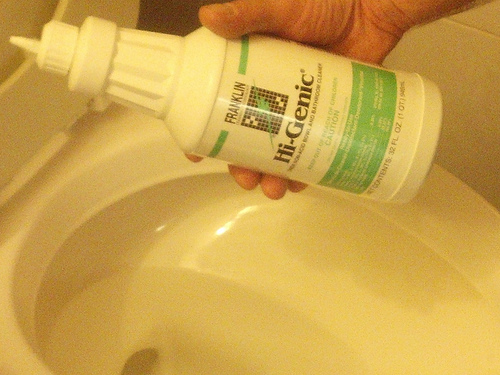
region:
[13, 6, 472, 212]
white green and black bottle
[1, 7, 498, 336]
toilet in background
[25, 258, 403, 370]
water in toilet bowl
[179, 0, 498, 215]
hand holding white bottle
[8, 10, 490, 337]
yellowish tint in background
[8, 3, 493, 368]
white toilet in background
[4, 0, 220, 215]
toilet seat put up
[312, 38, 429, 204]
green label on white bottle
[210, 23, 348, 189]
logo on white bottle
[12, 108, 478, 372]
clear water in toilet bowl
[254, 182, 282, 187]
section of two fingers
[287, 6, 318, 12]
section of a thumb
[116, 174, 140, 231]
inside of a sink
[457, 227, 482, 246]
edge of a sink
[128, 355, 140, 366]
hole on a sink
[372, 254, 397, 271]
a white sink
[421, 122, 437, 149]
bottom of a bottle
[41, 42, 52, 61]
tip of a bottle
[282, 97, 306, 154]
name of a white bottle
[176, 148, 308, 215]
four fingers holding bottle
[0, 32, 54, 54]
pointy tip of bottle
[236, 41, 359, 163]
writing on bottle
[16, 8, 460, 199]
white and green bottle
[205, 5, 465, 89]
hand holding bottle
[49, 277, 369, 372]
water in clean toilet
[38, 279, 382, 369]
clean water in toilet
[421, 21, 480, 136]
white wall by hand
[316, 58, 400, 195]
green block area on bottle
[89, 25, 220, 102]
neck of white bottle by toilet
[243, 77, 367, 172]
this is a bottle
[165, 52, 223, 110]
the bottle is white in color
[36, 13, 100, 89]
this is the lid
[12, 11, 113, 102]
the lid is closed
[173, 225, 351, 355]
this is a sink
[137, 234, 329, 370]
the sink is white in color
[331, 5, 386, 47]
this is a hand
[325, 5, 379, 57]
the hand is white in color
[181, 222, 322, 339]
the sink is clean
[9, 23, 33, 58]
the lid is sharp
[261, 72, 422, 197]
the label is green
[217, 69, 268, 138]
the word is franklin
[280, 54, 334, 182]
the bottle is hi-genic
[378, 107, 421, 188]
the contents are 32 fl oz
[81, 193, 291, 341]
this is a toilet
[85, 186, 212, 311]
the bowl is white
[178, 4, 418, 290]
hand holding a bottle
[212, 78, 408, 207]
black grid on logo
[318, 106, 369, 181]
the word is caution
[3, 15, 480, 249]
the bottle is fluted